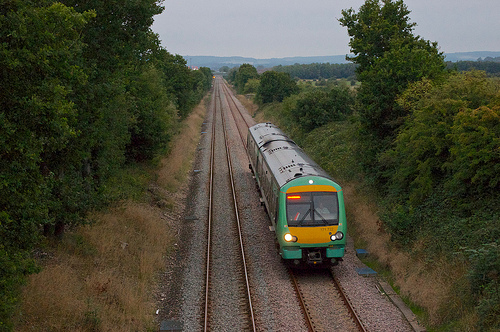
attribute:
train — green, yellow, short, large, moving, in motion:
[244, 120, 354, 273]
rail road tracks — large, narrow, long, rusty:
[170, 68, 414, 330]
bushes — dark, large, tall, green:
[1, 2, 496, 329]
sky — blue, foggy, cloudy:
[149, 1, 497, 71]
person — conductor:
[315, 201, 330, 216]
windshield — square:
[287, 192, 339, 225]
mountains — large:
[174, 52, 496, 72]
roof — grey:
[249, 121, 336, 182]